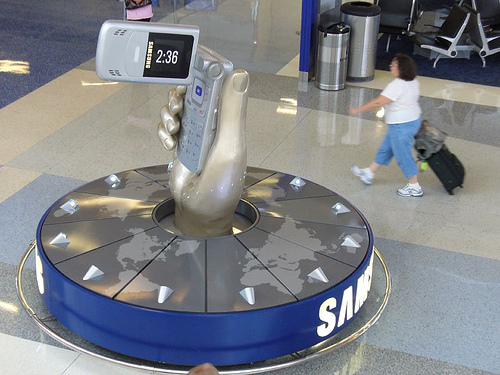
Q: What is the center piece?
A: A cell phone display.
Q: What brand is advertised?
A: Samsung.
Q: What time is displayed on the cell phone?
A: 2:36.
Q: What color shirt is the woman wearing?
A: White.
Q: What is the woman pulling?
A: A suitcase.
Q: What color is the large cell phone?
A: Silver.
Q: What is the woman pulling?
A: A suitcase.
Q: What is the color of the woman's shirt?
A: White.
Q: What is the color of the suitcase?
A: Black.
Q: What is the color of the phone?
A: Silver.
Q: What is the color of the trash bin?
A: Silver.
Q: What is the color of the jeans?
A: Blue.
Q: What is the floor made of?
A: Marble.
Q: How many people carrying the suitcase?
A: One.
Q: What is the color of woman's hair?
A: Brown.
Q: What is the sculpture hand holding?
A: A cellphone.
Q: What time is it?
A: 2:36.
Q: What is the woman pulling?
A: A carry-on suitcase.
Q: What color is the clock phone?
A: Grey.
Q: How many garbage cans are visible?
A: Two.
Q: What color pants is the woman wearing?
A: Blue.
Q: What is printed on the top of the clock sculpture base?
A: A world atlas.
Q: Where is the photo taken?
A: Terminal.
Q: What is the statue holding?
A: Cell phone.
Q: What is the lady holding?
A: Suitcase.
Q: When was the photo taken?
A: Daytime.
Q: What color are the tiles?
A: Blue grey and white.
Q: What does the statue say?
A: Samsung.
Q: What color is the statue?
A: Grey.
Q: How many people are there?
A: 1.